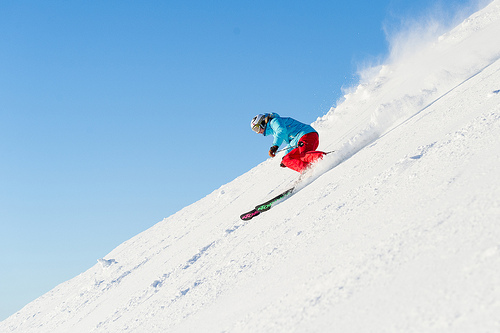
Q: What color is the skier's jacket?
A: Blue.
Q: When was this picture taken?
A: Wintertime.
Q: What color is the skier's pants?
A: Red.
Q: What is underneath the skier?
A: Snow.